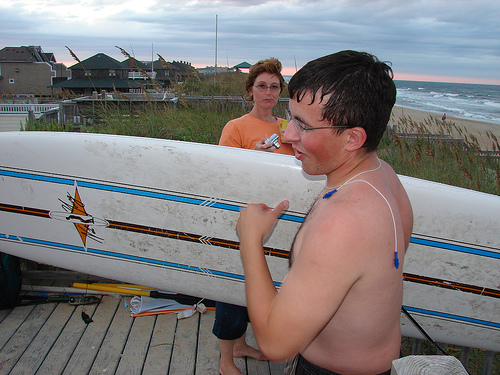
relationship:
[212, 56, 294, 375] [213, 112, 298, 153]
lady wearing shirt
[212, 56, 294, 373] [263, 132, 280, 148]
lady holding camera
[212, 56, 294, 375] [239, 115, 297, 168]
lady holding camera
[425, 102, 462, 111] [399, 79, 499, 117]
wave in water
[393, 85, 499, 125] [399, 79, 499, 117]
wave in water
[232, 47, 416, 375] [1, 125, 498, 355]
kid holds surfboard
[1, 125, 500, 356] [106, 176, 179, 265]
surfboard has stripes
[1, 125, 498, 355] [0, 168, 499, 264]
surfboard has stripe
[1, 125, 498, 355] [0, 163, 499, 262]
surfboard has stripe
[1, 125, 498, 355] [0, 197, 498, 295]
surfboard has stripe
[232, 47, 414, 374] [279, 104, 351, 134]
kid has glasses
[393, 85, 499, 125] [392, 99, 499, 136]
wave on shore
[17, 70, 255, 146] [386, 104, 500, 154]
grass on sand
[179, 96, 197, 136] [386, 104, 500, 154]
grass on sand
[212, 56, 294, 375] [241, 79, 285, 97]
lady with glasses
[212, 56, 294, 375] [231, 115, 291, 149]
lady with shirt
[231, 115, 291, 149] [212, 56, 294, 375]
shirt on lady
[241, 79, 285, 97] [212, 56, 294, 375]
glasses on lady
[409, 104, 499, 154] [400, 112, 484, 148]
sand on beach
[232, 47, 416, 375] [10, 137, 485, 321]
kid with surfboard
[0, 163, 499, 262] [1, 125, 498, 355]
stripe on surfboard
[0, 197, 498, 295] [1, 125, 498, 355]
stripe on surfboard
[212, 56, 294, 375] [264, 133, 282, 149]
lady with camera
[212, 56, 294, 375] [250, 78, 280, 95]
lady with glasses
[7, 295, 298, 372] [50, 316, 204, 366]
wooden deck with boarding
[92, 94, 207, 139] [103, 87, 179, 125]
bushes with leaves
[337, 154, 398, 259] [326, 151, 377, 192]
earplugs around neck